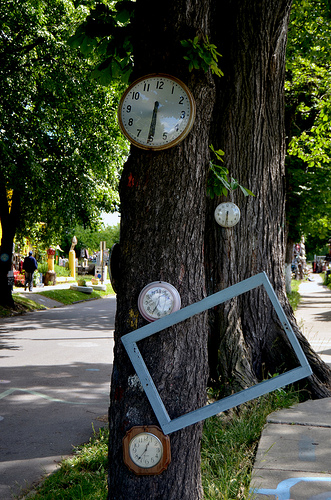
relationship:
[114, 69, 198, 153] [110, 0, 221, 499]
clock attached to tree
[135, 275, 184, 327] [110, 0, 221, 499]
clock attached to tree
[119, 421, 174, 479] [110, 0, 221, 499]
clock attached to tree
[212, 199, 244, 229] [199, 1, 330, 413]
clock attached to tree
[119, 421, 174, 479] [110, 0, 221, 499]
clock on tree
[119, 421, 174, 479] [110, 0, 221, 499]
clock at bottom of tree